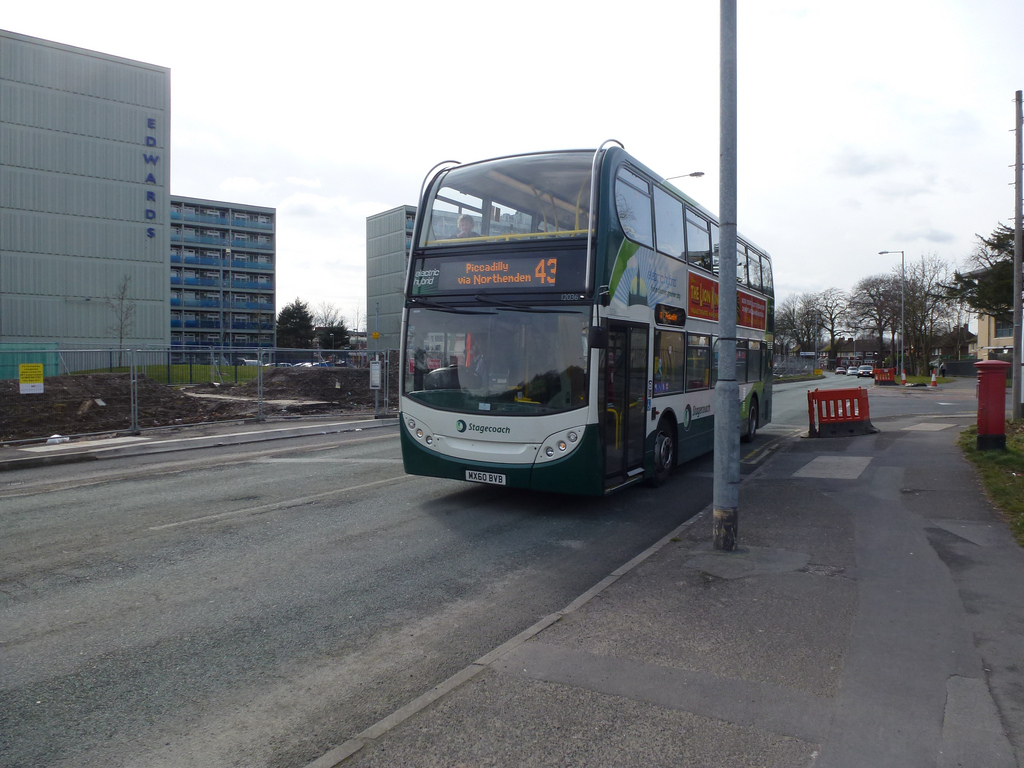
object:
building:
[169, 194, 278, 367]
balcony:
[183, 202, 230, 226]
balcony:
[230, 209, 273, 231]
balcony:
[184, 224, 231, 246]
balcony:
[230, 229, 274, 251]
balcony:
[183, 243, 222, 265]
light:
[877, 250, 890, 255]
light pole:
[889, 250, 906, 378]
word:
[142, 116, 161, 240]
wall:
[0, 26, 170, 392]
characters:
[545, 258, 558, 285]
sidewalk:
[301, 412, 1024, 768]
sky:
[9, 0, 1022, 215]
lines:
[145, 471, 414, 534]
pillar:
[972, 358, 1013, 451]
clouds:
[165, 17, 716, 141]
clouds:
[736, 24, 1015, 250]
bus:
[395, 139, 775, 504]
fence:
[0, 345, 402, 445]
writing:
[468, 421, 511, 434]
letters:
[501, 427, 506, 435]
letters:
[506, 425, 512, 434]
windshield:
[400, 297, 591, 417]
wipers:
[474, 294, 584, 314]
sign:
[436, 260, 556, 291]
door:
[603, 315, 649, 480]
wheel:
[633, 415, 676, 489]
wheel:
[739, 396, 759, 444]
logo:
[454, 418, 511, 433]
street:
[143, 405, 598, 693]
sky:
[0, 0, 1024, 341]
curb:
[444, 428, 813, 688]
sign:
[17, 362, 45, 395]